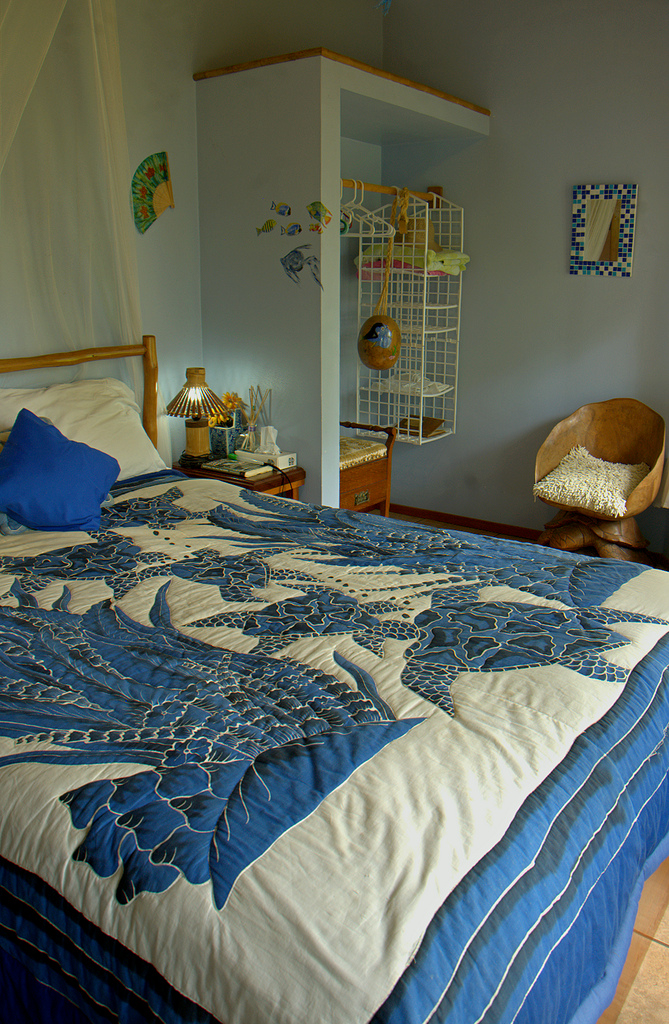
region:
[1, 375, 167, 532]
two pillows on top of a bed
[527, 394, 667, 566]
brown wood chair with white pillow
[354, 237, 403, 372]
brown egg hanging from rope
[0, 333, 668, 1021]
wood bed with turtle bedspread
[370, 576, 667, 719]
black and blue turtle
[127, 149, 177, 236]
green hand fan hanging on wall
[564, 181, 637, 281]
mirror with tiled frame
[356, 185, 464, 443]
white plastic hanging clothing rack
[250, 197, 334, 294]
fish decals on a white wall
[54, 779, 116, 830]
blue quilted fabric on the blanket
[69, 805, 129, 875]
blue quilted fabric on the blanket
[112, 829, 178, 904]
blue quilted fabric on the blanket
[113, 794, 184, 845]
blue quilted fabric on the blanket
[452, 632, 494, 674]
blue quilted fabric on the blanket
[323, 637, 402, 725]
blue quilted fabric on the blanket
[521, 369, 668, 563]
small chair against wall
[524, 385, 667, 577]
wooden chair is small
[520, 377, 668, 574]
small chair is wooden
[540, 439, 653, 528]
pillow in seat of chair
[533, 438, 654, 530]
pillow in chair is white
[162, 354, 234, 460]
small lamp on end table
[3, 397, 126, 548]
pillow on bed is blue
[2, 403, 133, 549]
pillow on bed is square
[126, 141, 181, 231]
fan hanging on wall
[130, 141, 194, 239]
green fan on the wall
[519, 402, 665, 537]
brown wooden chair against the wall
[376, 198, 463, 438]
plastic shelves hanging on a bar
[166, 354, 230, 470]
lamp on table by the bed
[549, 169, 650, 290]
mosaic tile mirror on the wall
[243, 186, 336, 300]
fish stickers on the wall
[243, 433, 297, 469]
box of tissues on the table by the bed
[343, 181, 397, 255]
hangers hanging on the rod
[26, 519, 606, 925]
blue and white bed spread on the bed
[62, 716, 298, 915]
floral design on bed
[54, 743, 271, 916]
floral design on bed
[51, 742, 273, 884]
floral design on bed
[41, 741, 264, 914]
floral design on bed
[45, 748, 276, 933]
floral design on bed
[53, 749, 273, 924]
floral design on bed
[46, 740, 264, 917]
floral design on bed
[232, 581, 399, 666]
Design on a bed spread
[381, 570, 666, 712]
Design on a bed spread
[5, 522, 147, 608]
Design on a bed spread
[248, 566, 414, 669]
Design on a bed spread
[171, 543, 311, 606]
Design on a bed spread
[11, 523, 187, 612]
Design on a bed spread